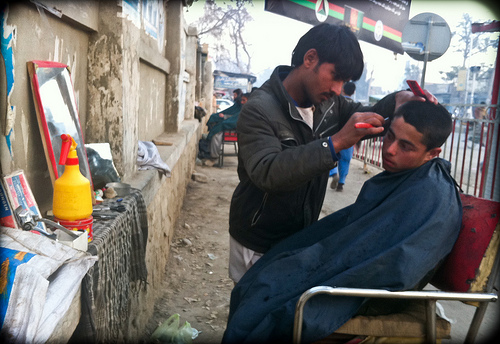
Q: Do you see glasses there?
A: No, there are no glasses.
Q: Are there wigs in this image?
A: No, there are no wigs.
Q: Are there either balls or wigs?
A: No, there are no wigs or balls.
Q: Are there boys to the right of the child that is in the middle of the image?
A: Yes, there is a boy to the right of the kid.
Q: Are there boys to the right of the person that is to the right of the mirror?
A: Yes, there is a boy to the right of the kid.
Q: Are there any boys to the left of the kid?
A: No, the boy is to the right of the kid.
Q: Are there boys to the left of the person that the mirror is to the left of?
A: No, the boy is to the right of the kid.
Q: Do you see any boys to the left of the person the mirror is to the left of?
A: No, the boy is to the right of the kid.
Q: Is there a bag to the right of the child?
A: No, there is a boy to the right of the child.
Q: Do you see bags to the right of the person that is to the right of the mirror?
A: No, there is a boy to the right of the child.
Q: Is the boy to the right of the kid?
A: Yes, the boy is to the right of the kid.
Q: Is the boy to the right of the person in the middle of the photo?
A: Yes, the boy is to the right of the kid.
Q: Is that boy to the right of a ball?
A: No, the boy is to the right of the kid.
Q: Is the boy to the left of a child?
A: No, the boy is to the right of a child.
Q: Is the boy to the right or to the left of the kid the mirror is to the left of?
A: The boy is to the right of the child.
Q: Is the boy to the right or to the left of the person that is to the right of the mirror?
A: The boy is to the right of the child.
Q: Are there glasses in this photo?
A: No, there are no glasses.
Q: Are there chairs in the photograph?
A: Yes, there is a chair.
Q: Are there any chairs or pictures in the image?
A: Yes, there is a chair.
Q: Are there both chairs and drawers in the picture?
A: No, there is a chair but no drawers.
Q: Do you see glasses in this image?
A: No, there are no glasses.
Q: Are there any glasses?
A: No, there are no glasses.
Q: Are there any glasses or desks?
A: No, there are no glasses or desks.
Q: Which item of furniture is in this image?
A: The piece of furniture is a chair.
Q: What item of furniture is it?
A: The piece of furniture is a chair.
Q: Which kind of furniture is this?
A: This is a chair.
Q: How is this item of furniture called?
A: This is a chair.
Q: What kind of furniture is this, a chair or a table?
A: This is a chair.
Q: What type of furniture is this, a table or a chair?
A: This is a chair.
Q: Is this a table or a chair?
A: This is a chair.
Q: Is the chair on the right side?
A: Yes, the chair is on the right of the image.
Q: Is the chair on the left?
A: No, the chair is on the right of the image.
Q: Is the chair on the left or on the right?
A: The chair is on the right of the image.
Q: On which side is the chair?
A: The chair is on the right of the image.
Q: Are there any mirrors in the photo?
A: Yes, there is a mirror.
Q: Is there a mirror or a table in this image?
A: Yes, there is a mirror.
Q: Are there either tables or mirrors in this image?
A: Yes, there is a mirror.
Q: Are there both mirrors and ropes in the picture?
A: No, there is a mirror but no ropes.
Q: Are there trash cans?
A: No, there are no trash cans.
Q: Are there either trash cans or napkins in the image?
A: No, there are no trash cans or napkins.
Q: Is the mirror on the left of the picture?
A: Yes, the mirror is on the left of the image.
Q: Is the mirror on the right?
A: No, the mirror is on the left of the image.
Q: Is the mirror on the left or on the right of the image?
A: The mirror is on the left of the image.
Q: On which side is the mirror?
A: The mirror is on the left of the image.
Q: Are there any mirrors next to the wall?
A: Yes, there is a mirror next to the wall.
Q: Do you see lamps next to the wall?
A: No, there is a mirror next to the wall.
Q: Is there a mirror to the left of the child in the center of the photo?
A: Yes, there is a mirror to the left of the kid.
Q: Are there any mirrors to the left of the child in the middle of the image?
A: Yes, there is a mirror to the left of the kid.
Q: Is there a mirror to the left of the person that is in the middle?
A: Yes, there is a mirror to the left of the kid.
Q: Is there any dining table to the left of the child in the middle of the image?
A: No, there is a mirror to the left of the child.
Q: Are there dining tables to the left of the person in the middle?
A: No, there is a mirror to the left of the child.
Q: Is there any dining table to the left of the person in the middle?
A: No, there is a mirror to the left of the child.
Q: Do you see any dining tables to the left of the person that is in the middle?
A: No, there is a mirror to the left of the child.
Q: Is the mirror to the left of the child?
A: Yes, the mirror is to the left of the child.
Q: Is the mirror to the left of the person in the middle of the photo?
A: Yes, the mirror is to the left of the child.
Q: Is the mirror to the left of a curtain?
A: No, the mirror is to the left of the child.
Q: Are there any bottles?
A: Yes, there is a bottle.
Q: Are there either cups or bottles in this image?
A: Yes, there is a bottle.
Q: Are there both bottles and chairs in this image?
A: Yes, there are both a bottle and a chair.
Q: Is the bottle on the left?
A: Yes, the bottle is on the left of the image.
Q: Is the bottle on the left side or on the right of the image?
A: The bottle is on the left of the image.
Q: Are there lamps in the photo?
A: No, there are no lamps.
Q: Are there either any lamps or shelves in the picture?
A: No, there are no lamps or shelves.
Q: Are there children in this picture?
A: Yes, there is a child.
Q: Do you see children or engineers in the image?
A: Yes, there is a child.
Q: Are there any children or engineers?
A: Yes, there is a child.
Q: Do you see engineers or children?
A: Yes, there is a child.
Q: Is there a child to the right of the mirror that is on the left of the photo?
A: Yes, there is a child to the right of the mirror.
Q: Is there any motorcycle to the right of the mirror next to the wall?
A: No, there is a child to the right of the mirror.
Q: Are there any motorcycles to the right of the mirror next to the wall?
A: No, there is a child to the right of the mirror.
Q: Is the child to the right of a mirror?
A: Yes, the child is to the right of a mirror.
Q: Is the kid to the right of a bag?
A: No, the kid is to the right of a mirror.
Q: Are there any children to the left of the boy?
A: Yes, there is a child to the left of the boy.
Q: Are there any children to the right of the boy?
A: No, the child is to the left of the boy.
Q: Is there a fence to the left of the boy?
A: No, there is a child to the left of the boy.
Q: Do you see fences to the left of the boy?
A: No, there is a child to the left of the boy.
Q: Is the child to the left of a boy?
A: Yes, the child is to the left of a boy.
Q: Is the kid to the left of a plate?
A: No, the kid is to the left of a boy.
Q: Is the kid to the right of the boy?
A: No, the kid is to the left of the boy.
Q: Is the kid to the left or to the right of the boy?
A: The kid is to the left of the boy.